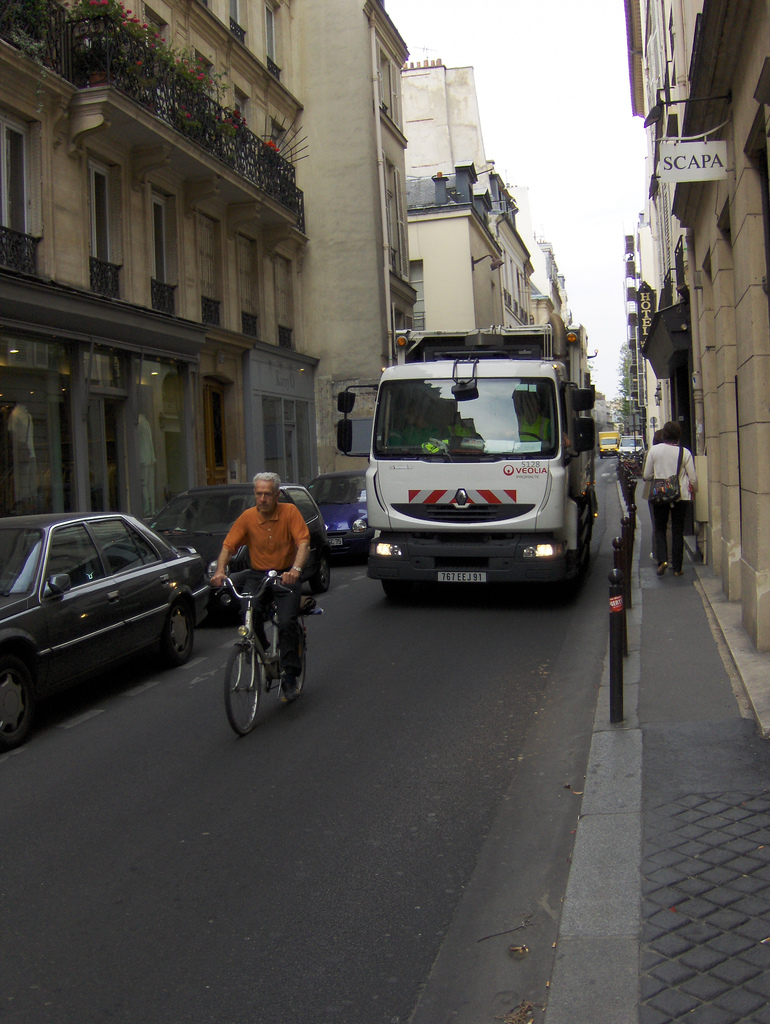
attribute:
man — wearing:
[214, 466, 348, 723]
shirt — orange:
[214, 491, 319, 594]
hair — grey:
[238, 453, 292, 499]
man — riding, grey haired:
[203, 461, 337, 712]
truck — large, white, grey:
[329, 350, 620, 621]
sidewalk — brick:
[619, 576, 721, 1008]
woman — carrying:
[629, 401, 714, 612]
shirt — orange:
[202, 498, 315, 586]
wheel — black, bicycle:
[204, 627, 285, 764]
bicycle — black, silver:
[188, 547, 319, 745]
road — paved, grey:
[7, 562, 609, 1021]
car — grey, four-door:
[1, 501, 209, 760]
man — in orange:
[203, 457, 323, 717]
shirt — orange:
[211, 499, 323, 592]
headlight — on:
[353, 508, 403, 575]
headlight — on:
[512, 518, 580, 576]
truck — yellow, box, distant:
[584, 411, 628, 475]